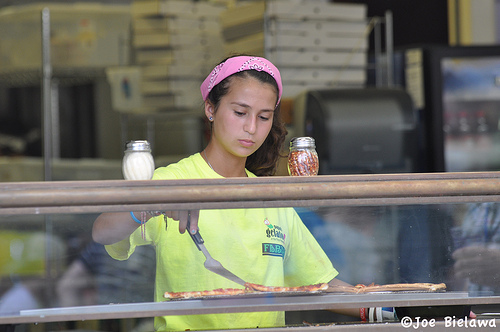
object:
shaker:
[286, 136, 322, 178]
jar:
[121, 138, 155, 181]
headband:
[199, 56, 282, 109]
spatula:
[186, 210, 257, 289]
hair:
[199, 53, 289, 158]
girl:
[94, 53, 478, 331]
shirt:
[103, 152, 340, 331]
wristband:
[361, 306, 383, 325]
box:
[129, 0, 369, 115]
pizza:
[162, 282, 328, 301]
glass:
[1, 201, 500, 331]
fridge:
[390, 43, 498, 300]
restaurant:
[2, 0, 498, 331]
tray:
[171, 290, 328, 300]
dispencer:
[292, 85, 418, 176]